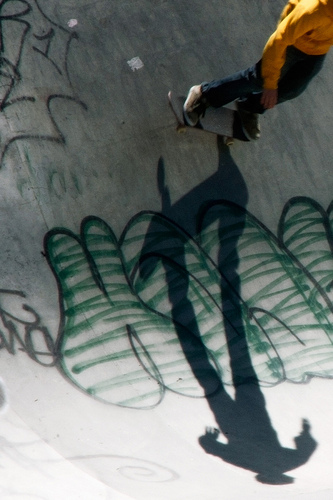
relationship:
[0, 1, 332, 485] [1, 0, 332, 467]
graffite on ramp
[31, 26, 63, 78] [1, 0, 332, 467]
graffite painted on ramp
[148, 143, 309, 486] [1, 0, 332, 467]
shadow on ramp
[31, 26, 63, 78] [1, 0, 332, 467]
graffite on ramp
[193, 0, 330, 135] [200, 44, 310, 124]
person wearing pants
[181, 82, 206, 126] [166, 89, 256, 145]
feet on skateboard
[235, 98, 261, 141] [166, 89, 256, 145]
feet on skateboard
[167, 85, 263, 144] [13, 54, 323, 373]
skateboard on ramp